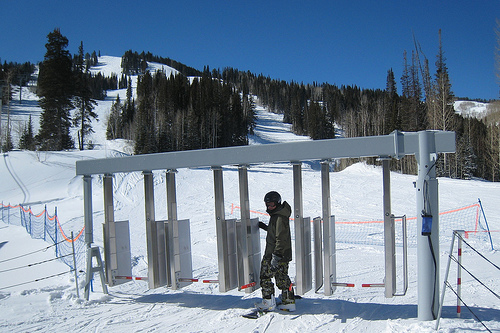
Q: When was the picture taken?
A: During the day.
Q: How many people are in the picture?
A: 1.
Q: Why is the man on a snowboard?
A: So he can snowboard.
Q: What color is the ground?
A: White.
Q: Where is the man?
A: On a ski slope.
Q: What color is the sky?
A: Blue.